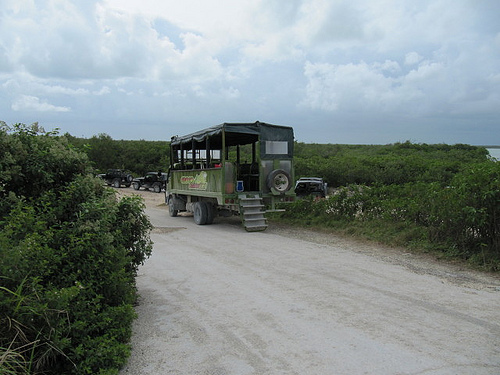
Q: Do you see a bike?
A: No, there are no bikes.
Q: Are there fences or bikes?
A: No, there are no bikes or fences.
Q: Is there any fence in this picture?
A: No, there are no fences.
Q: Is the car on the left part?
A: Yes, the car is on the left of the image.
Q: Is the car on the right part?
A: No, the car is on the left of the image.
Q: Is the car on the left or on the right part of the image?
A: The car is on the left of the image.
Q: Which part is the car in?
A: The car is on the left of the image.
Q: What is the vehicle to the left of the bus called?
A: The vehicle is a car.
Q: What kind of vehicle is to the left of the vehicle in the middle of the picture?
A: The vehicle is a car.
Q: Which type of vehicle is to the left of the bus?
A: The vehicle is a car.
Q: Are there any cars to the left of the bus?
A: Yes, there is a car to the left of the bus.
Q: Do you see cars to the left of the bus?
A: Yes, there is a car to the left of the bus.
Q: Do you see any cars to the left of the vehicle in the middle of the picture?
A: Yes, there is a car to the left of the bus.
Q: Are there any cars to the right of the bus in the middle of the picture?
A: No, the car is to the left of the bus.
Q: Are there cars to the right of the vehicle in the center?
A: No, the car is to the left of the bus.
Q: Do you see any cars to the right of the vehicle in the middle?
A: No, the car is to the left of the bus.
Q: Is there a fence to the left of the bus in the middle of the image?
A: No, there is a car to the left of the bus.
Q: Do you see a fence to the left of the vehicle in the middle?
A: No, there is a car to the left of the bus.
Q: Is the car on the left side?
A: Yes, the car is on the left of the image.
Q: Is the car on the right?
A: No, the car is on the left of the image.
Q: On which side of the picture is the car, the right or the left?
A: The car is on the left of the image.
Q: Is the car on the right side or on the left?
A: The car is on the left of the image.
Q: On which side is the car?
A: The car is on the left of the image.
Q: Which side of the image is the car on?
A: The car is on the left of the image.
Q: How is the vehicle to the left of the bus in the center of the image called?
A: The vehicle is a car.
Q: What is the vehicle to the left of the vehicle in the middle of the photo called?
A: The vehicle is a car.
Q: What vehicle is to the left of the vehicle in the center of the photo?
A: The vehicle is a car.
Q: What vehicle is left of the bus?
A: The vehicle is a car.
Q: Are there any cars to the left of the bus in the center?
A: Yes, there is a car to the left of the bus.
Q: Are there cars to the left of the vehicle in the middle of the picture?
A: Yes, there is a car to the left of the bus.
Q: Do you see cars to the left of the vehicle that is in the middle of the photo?
A: Yes, there is a car to the left of the bus.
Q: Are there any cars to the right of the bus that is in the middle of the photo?
A: No, the car is to the left of the bus.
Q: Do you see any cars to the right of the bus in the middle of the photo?
A: No, the car is to the left of the bus.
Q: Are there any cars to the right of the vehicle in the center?
A: No, the car is to the left of the bus.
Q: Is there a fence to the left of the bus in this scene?
A: No, there is a car to the left of the bus.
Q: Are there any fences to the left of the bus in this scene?
A: No, there is a car to the left of the bus.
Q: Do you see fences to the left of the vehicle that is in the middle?
A: No, there is a car to the left of the bus.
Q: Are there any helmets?
A: No, there are no helmets.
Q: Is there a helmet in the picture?
A: No, there are no helmets.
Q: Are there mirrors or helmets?
A: No, there are no helmets or mirrors.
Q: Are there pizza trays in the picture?
A: No, there are no pizza trays.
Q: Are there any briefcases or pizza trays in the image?
A: No, there are no pizza trays or briefcases.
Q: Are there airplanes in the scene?
A: No, there are no airplanes.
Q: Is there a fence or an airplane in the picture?
A: No, there are no airplanes or fences.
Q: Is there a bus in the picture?
A: Yes, there is a bus.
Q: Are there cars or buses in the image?
A: Yes, there is a bus.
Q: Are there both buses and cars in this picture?
A: Yes, there are both a bus and a car.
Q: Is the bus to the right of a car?
A: Yes, the bus is to the right of a car.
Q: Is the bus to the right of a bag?
A: No, the bus is to the right of a car.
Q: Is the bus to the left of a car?
A: No, the bus is to the right of a car.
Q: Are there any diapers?
A: No, there are no diapers.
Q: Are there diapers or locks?
A: No, there are no diapers or locks.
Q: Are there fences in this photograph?
A: No, there are no fences.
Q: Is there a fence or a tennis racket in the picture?
A: No, there are no fences or rackets.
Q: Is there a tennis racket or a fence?
A: No, there are no fences or rackets.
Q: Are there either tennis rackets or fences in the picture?
A: No, there are no fences or tennis rackets.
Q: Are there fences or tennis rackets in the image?
A: No, there are no fences or tennis rackets.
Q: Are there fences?
A: No, there are no fences.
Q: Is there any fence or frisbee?
A: No, there are no fences or frisbees.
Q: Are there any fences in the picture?
A: No, there are no fences.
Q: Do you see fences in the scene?
A: No, there are no fences.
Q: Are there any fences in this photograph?
A: No, there are no fences.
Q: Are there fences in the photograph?
A: No, there are no fences.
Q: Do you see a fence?
A: No, there are no fences.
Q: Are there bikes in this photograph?
A: No, there are no bikes.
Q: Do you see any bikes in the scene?
A: No, there are no bikes.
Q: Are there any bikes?
A: No, there are no bikes.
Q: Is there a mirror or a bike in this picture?
A: No, there are no bikes or mirrors.